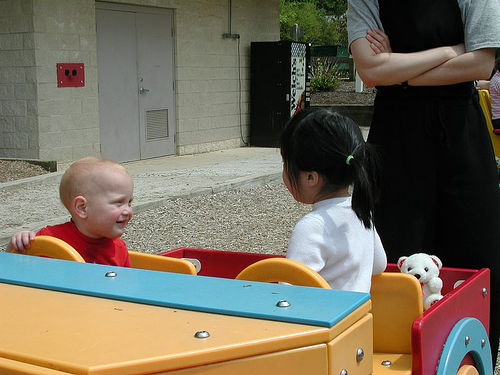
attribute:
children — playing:
[2, 101, 390, 292]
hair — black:
[280, 98, 402, 228]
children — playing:
[5, 122, 360, 285]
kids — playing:
[278, 104, 388, 294]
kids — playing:
[4, 155, 134, 263]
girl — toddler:
[268, 107, 388, 290]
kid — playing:
[0, 145, 148, 302]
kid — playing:
[248, 97, 393, 322]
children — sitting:
[20, 98, 446, 373]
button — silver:
[186, 328, 213, 346]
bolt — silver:
[195, 333, 208, 338]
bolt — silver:
[275, 301, 285, 308]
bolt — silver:
[103, 271, 115, 278]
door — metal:
[93, 5, 193, 167]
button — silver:
[193, 324, 212, 342]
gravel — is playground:
[117, 172, 322, 258]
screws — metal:
[275, 299, 289, 308]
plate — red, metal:
[54, 59, 86, 88]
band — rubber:
[344, 151, 352, 163]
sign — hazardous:
[53, 57, 86, 89]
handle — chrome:
[141, 70, 151, 96]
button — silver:
[268, 299, 293, 311]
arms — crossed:
[366, 26, 495, 86]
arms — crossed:
[350, 37, 467, 88]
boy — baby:
[11, 150, 153, 274]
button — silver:
[100, 270, 120, 279]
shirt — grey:
[346, 1, 498, 49]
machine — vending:
[244, 34, 311, 146]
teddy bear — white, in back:
[397, 250, 456, 314]